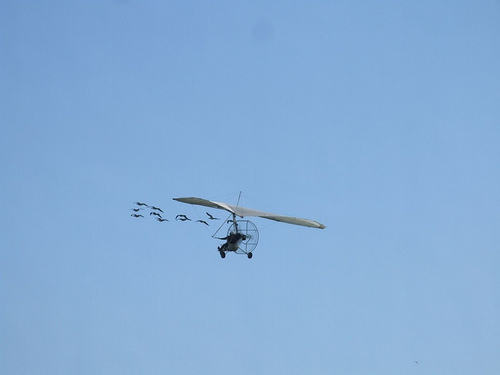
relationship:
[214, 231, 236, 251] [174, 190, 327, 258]
man on plane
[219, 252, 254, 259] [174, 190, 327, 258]
wheels on plane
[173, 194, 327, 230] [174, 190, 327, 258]
wings on plane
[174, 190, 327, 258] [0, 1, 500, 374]
plane in sky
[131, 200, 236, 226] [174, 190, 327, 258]
birds flying next to plane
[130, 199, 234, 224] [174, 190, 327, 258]
birds around plane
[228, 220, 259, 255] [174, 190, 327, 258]
fan on plane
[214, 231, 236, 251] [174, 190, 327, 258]
man in plane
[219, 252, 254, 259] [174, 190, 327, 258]
wheels under plane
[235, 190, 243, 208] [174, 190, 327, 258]
bar on plane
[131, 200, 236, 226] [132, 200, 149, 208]
birds has wings